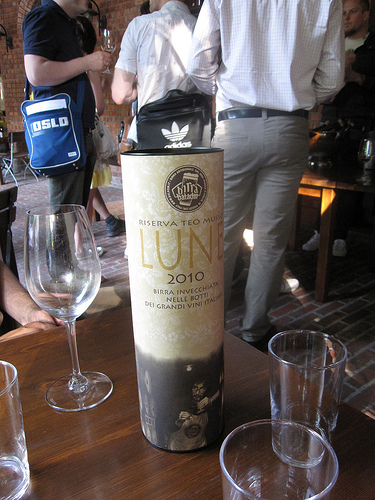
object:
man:
[19, 1, 106, 288]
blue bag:
[20, 78, 88, 178]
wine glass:
[98, 27, 118, 77]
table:
[297, 170, 373, 305]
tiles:
[341, 297, 370, 315]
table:
[0, 302, 375, 493]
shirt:
[183, 0, 349, 115]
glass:
[218, 417, 339, 496]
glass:
[0, 357, 31, 496]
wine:
[117, 142, 230, 455]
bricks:
[3, 58, 18, 76]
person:
[186, 0, 344, 349]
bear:
[103, 50, 111, 55]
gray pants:
[212, 114, 312, 348]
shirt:
[114, 0, 200, 143]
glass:
[266, 327, 351, 466]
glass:
[21, 201, 114, 413]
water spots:
[54, 235, 82, 274]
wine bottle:
[120, 147, 224, 451]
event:
[0, 0, 375, 500]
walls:
[1, 0, 23, 138]